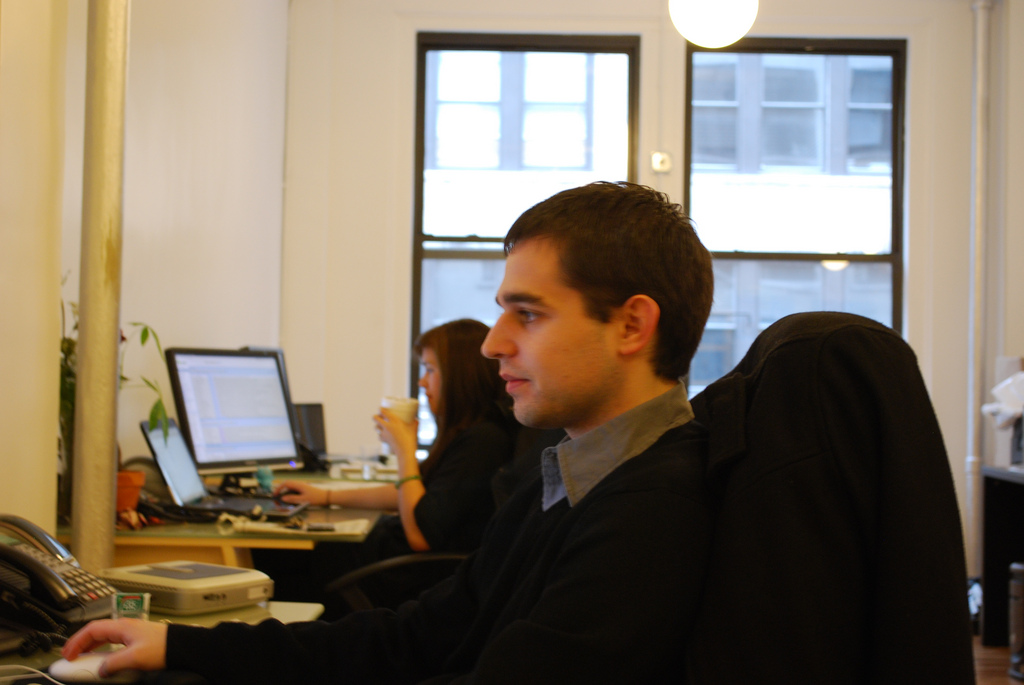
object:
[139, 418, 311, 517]
laptop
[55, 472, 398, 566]
table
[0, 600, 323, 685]
table